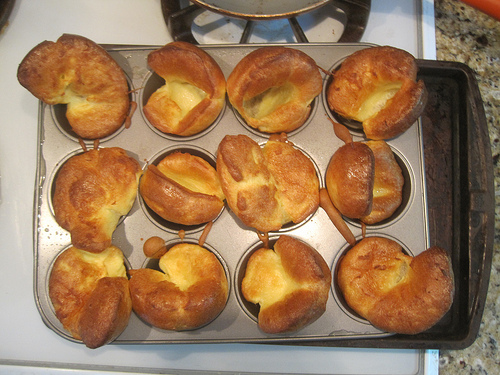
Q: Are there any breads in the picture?
A: Yes, there is a bread.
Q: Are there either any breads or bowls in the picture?
A: Yes, there is a bread.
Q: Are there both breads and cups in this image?
A: No, there is a bread but no cups.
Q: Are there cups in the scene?
A: No, there are no cups.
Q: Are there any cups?
A: No, there are no cups.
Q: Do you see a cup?
A: No, there are no cups.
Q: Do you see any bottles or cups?
A: No, there are no cups or bottles.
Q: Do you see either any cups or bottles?
A: No, there are no cups or bottles.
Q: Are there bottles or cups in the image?
A: No, there are no cups or bottles.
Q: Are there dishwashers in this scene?
A: No, there are no dishwashers.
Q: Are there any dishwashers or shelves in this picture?
A: No, there are no dishwashers or shelves.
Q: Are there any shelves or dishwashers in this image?
A: No, there are no dishwashers or shelves.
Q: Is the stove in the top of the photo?
A: Yes, the stove is in the top of the image.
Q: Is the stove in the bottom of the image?
A: No, the stove is in the top of the image.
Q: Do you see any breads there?
A: Yes, there is a bread.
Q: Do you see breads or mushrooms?
A: Yes, there is a bread.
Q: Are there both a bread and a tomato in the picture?
A: No, there is a bread but no tomatoes.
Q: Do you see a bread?
A: Yes, there is a bread.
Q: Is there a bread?
A: Yes, there is a bread.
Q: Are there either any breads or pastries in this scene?
A: Yes, there is a bread.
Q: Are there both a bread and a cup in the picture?
A: No, there is a bread but no cups.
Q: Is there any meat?
A: No, there is no meat.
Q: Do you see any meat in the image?
A: No, there is no meat.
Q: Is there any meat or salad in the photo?
A: No, there are no meat or salad.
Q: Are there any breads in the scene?
A: Yes, there is a bread.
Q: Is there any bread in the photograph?
A: Yes, there is a bread.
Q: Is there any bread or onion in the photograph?
A: Yes, there is a bread.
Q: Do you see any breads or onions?
A: Yes, there is a bread.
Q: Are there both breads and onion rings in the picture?
A: No, there is a bread but no onion rings.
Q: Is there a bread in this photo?
A: Yes, there is a bread.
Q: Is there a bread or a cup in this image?
A: Yes, there is a bread.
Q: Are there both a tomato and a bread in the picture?
A: No, there is a bread but no tomatoes.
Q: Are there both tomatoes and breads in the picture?
A: No, there is a bread but no tomatoes.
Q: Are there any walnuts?
A: No, there are no walnuts.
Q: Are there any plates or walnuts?
A: No, there are no walnuts or plates.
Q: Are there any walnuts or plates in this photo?
A: No, there are no walnuts or plates.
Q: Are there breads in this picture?
A: Yes, there is a bread.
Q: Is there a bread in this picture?
A: Yes, there is a bread.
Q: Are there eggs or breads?
A: Yes, there is a bread.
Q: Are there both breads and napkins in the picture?
A: No, there is a bread but no napkins.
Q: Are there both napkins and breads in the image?
A: No, there is a bread but no napkins.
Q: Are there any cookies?
A: No, there are no cookies.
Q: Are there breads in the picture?
A: Yes, there is a bread.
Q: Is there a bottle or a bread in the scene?
A: Yes, there is a bread.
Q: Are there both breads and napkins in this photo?
A: No, there is a bread but no napkins.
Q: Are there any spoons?
A: No, there are no spoons.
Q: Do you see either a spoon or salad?
A: No, there are no spoons or salad.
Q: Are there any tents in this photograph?
A: No, there are no tents.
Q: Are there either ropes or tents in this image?
A: No, there are no tents or ropes.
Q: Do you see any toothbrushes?
A: No, there are no toothbrushes.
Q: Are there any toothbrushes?
A: No, there are no toothbrushes.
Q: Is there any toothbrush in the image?
A: No, there are no toothbrushes.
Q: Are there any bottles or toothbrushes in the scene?
A: No, there are no toothbrushes or bottles.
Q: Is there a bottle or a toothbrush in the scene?
A: No, there are no toothbrushes or bottles.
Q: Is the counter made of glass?
A: No, the counter is made of granite.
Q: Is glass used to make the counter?
A: No, the counter is made of granite.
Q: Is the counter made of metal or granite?
A: The counter is made of granite.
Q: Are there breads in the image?
A: Yes, there is a bread.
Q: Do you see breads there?
A: Yes, there is a bread.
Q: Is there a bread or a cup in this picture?
A: Yes, there is a bread.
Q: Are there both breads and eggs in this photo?
A: No, there is a bread but no eggs.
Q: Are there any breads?
A: Yes, there is a bread.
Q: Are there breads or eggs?
A: Yes, there is a bread.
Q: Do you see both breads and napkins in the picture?
A: No, there is a bread but no napkins.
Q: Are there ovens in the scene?
A: Yes, there is an oven.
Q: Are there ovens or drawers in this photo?
A: Yes, there is an oven.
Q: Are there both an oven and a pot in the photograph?
A: No, there is an oven but no pots.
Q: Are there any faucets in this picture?
A: No, there are no faucets.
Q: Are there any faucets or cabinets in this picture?
A: No, there are no faucets or cabinets.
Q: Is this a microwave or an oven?
A: This is an oven.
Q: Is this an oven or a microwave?
A: This is an oven.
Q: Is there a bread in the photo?
A: Yes, there is a bread.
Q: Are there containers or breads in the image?
A: Yes, there is a bread.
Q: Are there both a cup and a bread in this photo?
A: No, there is a bread but no cups.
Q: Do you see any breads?
A: Yes, there is a bread.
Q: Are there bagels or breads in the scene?
A: Yes, there is a bread.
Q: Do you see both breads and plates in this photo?
A: No, there is a bread but no plates.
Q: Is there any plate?
A: No, there are no plates.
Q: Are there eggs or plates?
A: No, there are no plates or eggs.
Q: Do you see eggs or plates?
A: No, there are no plates or eggs.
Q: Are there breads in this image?
A: Yes, there is a bread.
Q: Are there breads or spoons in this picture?
A: Yes, there is a bread.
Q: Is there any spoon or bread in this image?
A: Yes, there is a bread.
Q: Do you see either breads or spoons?
A: Yes, there is a bread.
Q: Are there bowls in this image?
A: No, there are no bowls.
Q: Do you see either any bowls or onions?
A: No, there are no bowls or onions.